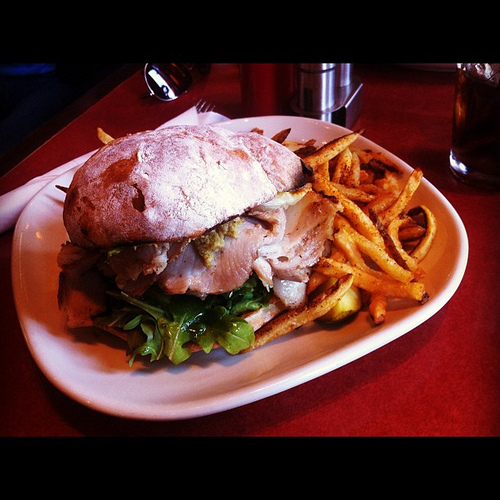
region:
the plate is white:
[155, 294, 266, 456]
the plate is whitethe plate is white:
[177, 395, 238, 482]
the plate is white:
[130, 305, 233, 428]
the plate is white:
[178, 360, 253, 495]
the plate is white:
[105, 290, 202, 413]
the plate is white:
[161, 356, 211, 429]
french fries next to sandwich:
[252, 115, 447, 330]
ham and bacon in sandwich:
[112, 187, 362, 319]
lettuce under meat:
[103, 269, 263, 360]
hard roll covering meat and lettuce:
[76, 130, 305, 348]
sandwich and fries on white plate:
[49, 111, 444, 361]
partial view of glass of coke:
[451, 55, 496, 180]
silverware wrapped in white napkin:
[0, 86, 230, 243]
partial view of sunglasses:
[138, 50, 209, 104]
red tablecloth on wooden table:
[0, 57, 499, 432]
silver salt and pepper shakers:
[289, 61, 368, 124]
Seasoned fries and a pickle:
[309, 133, 469, 340]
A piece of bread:
[37, 135, 288, 247]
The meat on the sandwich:
[99, 253, 287, 297]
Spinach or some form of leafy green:
[93, 276, 280, 372]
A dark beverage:
[427, 56, 493, 195]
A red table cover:
[307, 321, 456, 447]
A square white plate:
[1, 140, 476, 456]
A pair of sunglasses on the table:
[124, 51, 237, 121]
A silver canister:
[199, 43, 405, 148]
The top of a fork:
[128, 101, 248, 143]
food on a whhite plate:
[12, 112, 475, 415]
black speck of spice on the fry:
[369, 256, 381, 263]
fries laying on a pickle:
[299, 256, 376, 326]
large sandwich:
[45, 121, 313, 358]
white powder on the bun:
[135, 148, 215, 201]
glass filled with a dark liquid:
[424, 59, 499, 187]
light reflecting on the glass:
[444, 143, 474, 178]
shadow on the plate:
[13, 246, 63, 333]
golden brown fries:
[313, 140, 441, 315]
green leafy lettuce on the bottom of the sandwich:
[101, 286, 261, 366]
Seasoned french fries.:
[305, 150, 416, 277]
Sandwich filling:
[158, 220, 301, 296]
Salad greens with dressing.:
[77, 295, 260, 351]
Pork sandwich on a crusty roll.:
[32, 120, 329, 358]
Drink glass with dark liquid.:
[446, 57, 497, 210]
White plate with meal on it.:
[10, 98, 473, 431]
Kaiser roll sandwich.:
[77, 135, 275, 242]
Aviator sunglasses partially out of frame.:
[132, 57, 227, 99]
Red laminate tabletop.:
[380, 356, 492, 447]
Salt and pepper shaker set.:
[278, 56, 372, 128]